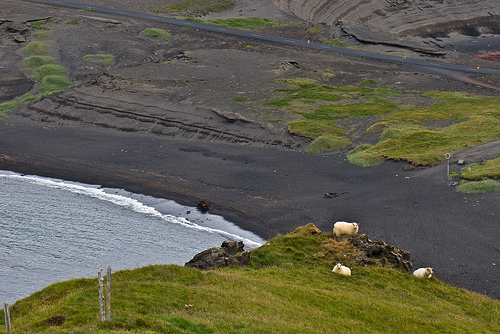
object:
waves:
[0, 171, 263, 251]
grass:
[383, 106, 473, 151]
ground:
[0, 0, 500, 334]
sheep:
[413, 266, 434, 278]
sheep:
[332, 263, 352, 277]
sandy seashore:
[1, 0, 500, 297]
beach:
[0, 0, 500, 334]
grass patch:
[276, 76, 396, 116]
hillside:
[2, 222, 498, 332]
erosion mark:
[7, 71, 306, 153]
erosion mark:
[269, 0, 499, 57]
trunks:
[105, 265, 112, 323]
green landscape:
[0, 233, 499, 332]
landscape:
[0, 0, 500, 334]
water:
[0, 170, 263, 307]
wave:
[2, 170, 268, 253]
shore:
[0, 123, 268, 256]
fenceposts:
[97, 264, 106, 322]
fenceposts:
[106, 265, 111, 322]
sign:
[444, 152, 450, 159]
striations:
[29, 87, 302, 152]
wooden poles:
[106, 265, 112, 322]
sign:
[475, 66, 481, 70]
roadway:
[15, 0, 500, 79]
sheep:
[332, 218, 358, 238]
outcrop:
[182, 240, 254, 275]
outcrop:
[348, 232, 416, 273]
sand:
[3, 0, 496, 299]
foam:
[42, 174, 160, 217]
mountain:
[2, 220, 495, 330]